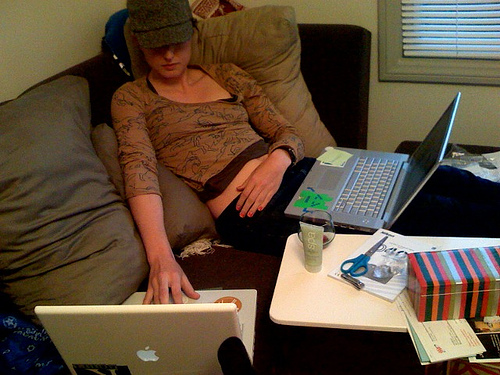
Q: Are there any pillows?
A: Yes, there is a pillow.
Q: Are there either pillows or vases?
A: Yes, there is a pillow.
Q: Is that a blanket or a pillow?
A: That is a pillow.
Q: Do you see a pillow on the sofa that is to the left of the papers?
A: Yes, there is a pillow on the sofa.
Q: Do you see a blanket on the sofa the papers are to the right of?
A: No, there is a pillow on the sofa.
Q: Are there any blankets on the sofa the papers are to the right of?
A: No, there is a pillow on the sofa.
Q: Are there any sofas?
A: Yes, there is a sofa.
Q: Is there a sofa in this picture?
A: Yes, there is a sofa.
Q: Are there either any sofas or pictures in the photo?
A: Yes, there is a sofa.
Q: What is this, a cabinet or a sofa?
A: This is a sofa.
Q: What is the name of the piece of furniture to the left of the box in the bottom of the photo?
A: The piece of furniture is a sofa.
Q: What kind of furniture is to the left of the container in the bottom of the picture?
A: The piece of furniture is a sofa.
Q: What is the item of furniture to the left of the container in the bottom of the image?
A: The piece of furniture is a sofa.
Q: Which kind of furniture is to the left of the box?
A: The piece of furniture is a sofa.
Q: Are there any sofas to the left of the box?
A: Yes, there is a sofa to the left of the box.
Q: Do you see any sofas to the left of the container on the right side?
A: Yes, there is a sofa to the left of the box.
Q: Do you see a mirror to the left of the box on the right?
A: No, there is a sofa to the left of the box.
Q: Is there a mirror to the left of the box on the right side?
A: No, there is a sofa to the left of the box.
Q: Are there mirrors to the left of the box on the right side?
A: No, there is a sofa to the left of the box.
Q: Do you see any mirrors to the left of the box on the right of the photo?
A: No, there is a sofa to the left of the box.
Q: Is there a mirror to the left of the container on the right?
A: No, there is a sofa to the left of the box.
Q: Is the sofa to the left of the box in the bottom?
A: Yes, the sofa is to the left of the box.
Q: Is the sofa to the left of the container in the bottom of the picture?
A: Yes, the sofa is to the left of the box.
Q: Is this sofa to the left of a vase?
A: No, the sofa is to the left of the box.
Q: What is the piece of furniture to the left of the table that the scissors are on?
A: The piece of furniture is a sofa.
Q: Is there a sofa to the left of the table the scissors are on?
A: Yes, there is a sofa to the left of the table.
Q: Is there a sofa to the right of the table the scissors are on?
A: No, the sofa is to the left of the table.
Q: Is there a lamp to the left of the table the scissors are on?
A: No, there is a sofa to the left of the table.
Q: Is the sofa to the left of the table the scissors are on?
A: Yes, the sofa is to the left of the table.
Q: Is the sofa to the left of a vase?
A: No, the sofa is to the left of the table.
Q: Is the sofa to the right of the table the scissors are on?
A: No, the sofa is to the left of the table.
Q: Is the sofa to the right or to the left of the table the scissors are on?
A: The sofa is to the left of the table.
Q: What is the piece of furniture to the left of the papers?
A: The piece of furniture is a sofa.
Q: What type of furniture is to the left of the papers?
A: The piece of furniture is a sofa.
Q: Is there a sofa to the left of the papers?
A: Yes, there is a sofa to the left of the papers.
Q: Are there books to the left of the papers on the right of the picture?
A: No, there is a sofa to the left of the papers.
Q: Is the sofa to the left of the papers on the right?
A: Yes, the sofa is to the left of the papers.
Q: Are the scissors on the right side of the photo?
A: Yes, the scissors are on the right of the image.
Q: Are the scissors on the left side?
A: No, the scissors are on the right of the image.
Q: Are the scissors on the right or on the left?
A: The scissors are on the right of the image.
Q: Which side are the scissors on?
A: The scissors are on the right of the image.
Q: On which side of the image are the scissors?
A: The scissors are on the right of the image.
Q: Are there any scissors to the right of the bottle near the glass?
A: Yes, there are scissors to the right of the bottle.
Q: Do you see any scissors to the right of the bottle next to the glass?
A: Yes, there are scissors to the right of the bottle.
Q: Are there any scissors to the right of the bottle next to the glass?
A: Yes, there are scissors to the right of the bottle.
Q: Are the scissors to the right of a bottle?
A: Yes, the scissors are to the right of a bottle.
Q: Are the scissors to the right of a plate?
A: No, the scissors are to the right of a bottle.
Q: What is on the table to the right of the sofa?
A: The scissors are on the table.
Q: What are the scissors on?
A: The scissors are on the table.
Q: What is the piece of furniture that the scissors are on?
A: The piece of furniture is a table.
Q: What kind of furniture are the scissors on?
A: The scissors are on the table.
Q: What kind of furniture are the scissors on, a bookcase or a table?
A: The scissors are on a table.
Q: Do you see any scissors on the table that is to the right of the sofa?
A: Yes, there are scissors on the table.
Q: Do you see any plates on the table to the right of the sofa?
A: No, there are scissors on the table.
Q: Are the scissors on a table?
A: Yes, the scissors are on a table.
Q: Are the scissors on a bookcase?
A: No, the scissors are on a table.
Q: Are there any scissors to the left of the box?
A: Yes, there are scissors to the left of the box.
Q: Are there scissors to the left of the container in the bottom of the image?
A: Yes, there are scissors to the left of the box.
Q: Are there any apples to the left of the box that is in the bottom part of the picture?
A: No, there are scissors to the left of the box.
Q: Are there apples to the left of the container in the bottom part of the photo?
A: No, there are scissors to the left of the box.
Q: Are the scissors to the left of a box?
A: Yes, the scissors are to the left of a box.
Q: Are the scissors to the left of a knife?
A: No, the scissors are to the left of a box.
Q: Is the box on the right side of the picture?
A: Yes, the box is on the right of the image.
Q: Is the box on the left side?
A: No, the box is on the right of the image.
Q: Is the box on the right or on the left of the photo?
A: The box is on the right of the image.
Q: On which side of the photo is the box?
A: The box is on the right of the image.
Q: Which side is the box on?
A: The box is on the right of the image.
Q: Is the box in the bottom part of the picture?
A: Yes, the box is in the bottom of the image.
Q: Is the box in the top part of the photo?
A: No, the box is in the bottom of the image.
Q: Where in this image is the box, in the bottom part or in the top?
A: The box is in the bottom of the image.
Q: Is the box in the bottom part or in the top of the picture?
A: The box is in the bottom of the image.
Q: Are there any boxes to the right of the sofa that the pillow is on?
A: Yes, there is a box to the right of the sofa.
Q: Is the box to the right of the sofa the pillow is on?
A: Yes, the box is to the right of the sofa.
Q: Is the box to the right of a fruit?
A: No, the box is to the right of the sofa.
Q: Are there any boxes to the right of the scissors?
A: Yes, there is a box to the right of the scissors.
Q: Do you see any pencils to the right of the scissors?
A: No, there is a box to the right of the scissors.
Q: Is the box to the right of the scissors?
A: Yes, the box is to the right of the scissors.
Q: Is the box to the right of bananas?
A: No, the box is to the right of the scissors.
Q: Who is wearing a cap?
A: The girl is wearing a cap.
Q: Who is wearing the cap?
A: The girl is wearing a cap.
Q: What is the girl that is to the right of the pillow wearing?
A: The girl is wearing a cap.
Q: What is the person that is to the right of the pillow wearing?
A: The girl is wearing a cap.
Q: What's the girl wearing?
A: The girl is wearing a cap.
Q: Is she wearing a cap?
A: Yes, the girl is wearing a cap.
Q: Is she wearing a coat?
A: No, the girl is wearing a cap.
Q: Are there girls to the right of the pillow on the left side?
A: Yes, there is a girl to the right of the pillow.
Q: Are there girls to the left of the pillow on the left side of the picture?
A: No, the girl is to the right of the pillow.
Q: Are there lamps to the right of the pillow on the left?
A: No, there is a girl to the right of the pillow.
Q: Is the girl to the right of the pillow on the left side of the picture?
A: Yes, the girl is to the right of the pillow.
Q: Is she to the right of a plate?
A: No, the girl is to the right of the pillow.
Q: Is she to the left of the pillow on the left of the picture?
A: No, the girl is to the right of the pillow.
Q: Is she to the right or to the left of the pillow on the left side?
A: The girl is to the right of the pillow.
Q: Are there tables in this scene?
A: Yes, there is a table.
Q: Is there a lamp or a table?
A: Yes, there is a table.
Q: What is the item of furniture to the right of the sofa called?
A: The piece of furniture is a table.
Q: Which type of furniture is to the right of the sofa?
A: The piece of furniture is a table.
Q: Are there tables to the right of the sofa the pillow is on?
A: Yes, there is a table to the right of the sofa.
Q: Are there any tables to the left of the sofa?
A: No, the table is to the right of the sofa.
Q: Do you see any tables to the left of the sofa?
A: No, the table is to the right of the sofa.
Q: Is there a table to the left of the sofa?
A: No, the table is to the right of the sofa.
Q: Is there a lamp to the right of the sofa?
A: No, there is a table to the right of the sofa.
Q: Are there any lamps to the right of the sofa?
A: No, there is a table to the right of the sofa.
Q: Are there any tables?
A: Yes, there is a table.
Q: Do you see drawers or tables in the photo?
A: Yes, there is a table.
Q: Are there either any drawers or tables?
A: Yes, there is a table.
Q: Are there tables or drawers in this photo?
A: Yes, there is a table.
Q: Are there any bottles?
A: Yes, there is a bottle.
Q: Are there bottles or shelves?
A: Yes, there is a bottle.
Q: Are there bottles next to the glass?
A: Yes, there is a bottle next to the glass.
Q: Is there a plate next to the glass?
A: No, there is a bottle next to the glass.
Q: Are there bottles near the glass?
A: Yes, there is a bottle near the glass.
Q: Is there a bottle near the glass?
A: Yes, there is a bottle near the glass.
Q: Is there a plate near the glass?
A: No, there is a bottle near the glass.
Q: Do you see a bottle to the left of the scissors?
A: Yes, there is a bottle to the left of the scissors.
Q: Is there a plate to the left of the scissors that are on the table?
A: No, there is a bottle to the left of the scissors.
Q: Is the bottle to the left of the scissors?
A: Yes, the bottle is to the left of the scissors.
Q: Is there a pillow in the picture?
A: Yes, there is a pillow.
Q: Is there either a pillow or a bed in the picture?
A: Yes, there is a pillow.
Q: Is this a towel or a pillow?
A: This is a pillow.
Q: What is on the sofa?
A: The pillow is on the sofa.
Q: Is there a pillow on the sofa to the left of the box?
A: Yes, there is a pillow on the sofa.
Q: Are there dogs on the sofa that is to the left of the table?
A: No, there is a pillow on the sofa.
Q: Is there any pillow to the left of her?
A: Yes, there is a pillow to the left of the girl.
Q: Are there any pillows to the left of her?
A: Yes, there is a pillow to the left of the girl.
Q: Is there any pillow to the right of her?
A: No, the pillow is to the left of the girl.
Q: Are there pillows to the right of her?
A: No, the pillow is to the left of the girl.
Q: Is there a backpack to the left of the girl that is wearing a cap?
A: No, there is a pillow to the left of the girl.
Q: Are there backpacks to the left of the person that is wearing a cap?
A: No, there is a pillow to the left of the girl.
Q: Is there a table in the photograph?
A: Yes, there is a table.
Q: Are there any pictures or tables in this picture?
A: Yes, there is a table.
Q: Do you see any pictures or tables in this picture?
A: Yes, there is a table.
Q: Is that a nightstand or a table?
A: That is a table.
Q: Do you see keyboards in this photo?
A: Yes, there is a keyboard.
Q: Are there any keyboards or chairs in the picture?
A: Yes, there is a keyboard.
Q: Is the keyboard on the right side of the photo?
A: Yes, the keyboard is on the right of the image.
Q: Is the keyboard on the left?
A: No, the keyboard is on the right of the image.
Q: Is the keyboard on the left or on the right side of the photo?
A: The keyboard is on the right of the image.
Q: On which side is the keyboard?
A: The keyboard is on the right of the image.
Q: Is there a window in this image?
A: Yes, there is a window.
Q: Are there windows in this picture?
A: Yes, there is a window.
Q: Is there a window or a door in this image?
A: Yes, there is a window.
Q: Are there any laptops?
A: Yes, there is a laptop.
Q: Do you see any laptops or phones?
A: Yes, there is a laptop.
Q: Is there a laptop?
A: Yes, there is a laptop.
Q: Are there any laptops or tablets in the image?
A: Yes, there is a laptop.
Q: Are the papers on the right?
A: Yes, the papers are on the right of the image.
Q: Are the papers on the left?
A: No, the papers are on the right of the image.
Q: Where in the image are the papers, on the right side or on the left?
A: The papers are on the right of the image.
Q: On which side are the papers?
A: The papers are on the right of the image.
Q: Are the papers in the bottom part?
A: Yes, the papers are in the bottom of the image.